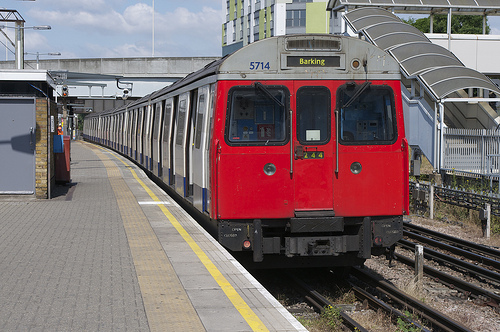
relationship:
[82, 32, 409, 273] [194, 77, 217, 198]
train with grafitti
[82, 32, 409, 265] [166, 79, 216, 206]
train with grafitti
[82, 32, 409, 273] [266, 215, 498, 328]
train on tracks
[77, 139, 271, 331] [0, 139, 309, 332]
line on road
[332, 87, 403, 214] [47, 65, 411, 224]
doors on train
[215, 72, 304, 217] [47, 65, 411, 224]
doors on train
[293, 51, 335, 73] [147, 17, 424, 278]
green location on train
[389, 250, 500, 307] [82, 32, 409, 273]
railway track under train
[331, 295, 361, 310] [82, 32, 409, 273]
grass under train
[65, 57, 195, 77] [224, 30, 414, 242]
bridge over train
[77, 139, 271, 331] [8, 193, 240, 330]
line on road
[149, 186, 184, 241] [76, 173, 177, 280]
line on road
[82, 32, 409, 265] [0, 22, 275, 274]
train at station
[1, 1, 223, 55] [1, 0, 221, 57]
clouds in sky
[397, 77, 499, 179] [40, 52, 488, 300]
stairs at station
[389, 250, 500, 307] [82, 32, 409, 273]
railway track for train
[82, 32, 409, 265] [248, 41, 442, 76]
train with graffiti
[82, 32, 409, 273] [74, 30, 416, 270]
train with grafitti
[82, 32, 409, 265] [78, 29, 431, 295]
train with grafitti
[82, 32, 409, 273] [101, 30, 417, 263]
train with grafitti